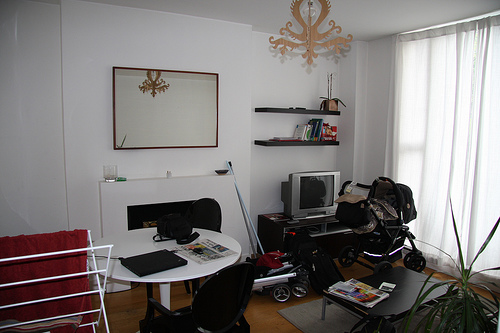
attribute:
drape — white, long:
[375, 14, 497, 271]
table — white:
[80, 224, 240, 317]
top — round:
[88, 227, 240, 282]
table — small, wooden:
[321, 265, 458, 332]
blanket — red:
[2, 226, 102, 329]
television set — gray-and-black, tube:
[285, 152, 332, 230]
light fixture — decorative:
[267, 2, 352, 62]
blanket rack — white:
[0, 233, 115, 331]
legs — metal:
[318, 294, 330, 323]